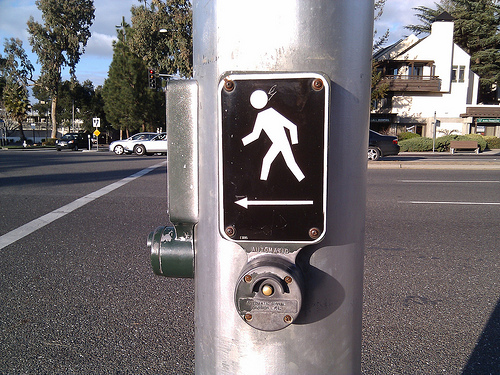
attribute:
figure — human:
[240, 90, 304, 182]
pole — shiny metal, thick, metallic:
[190, 0, 372, 371]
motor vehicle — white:
[134, 131, 166, 154]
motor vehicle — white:
[109, 130, 163, 154]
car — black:
[54, 130, 92, 150]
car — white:
[130, 134, 165, 157]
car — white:
[110, 129, 162, 157]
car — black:
[364, 128, 399, 161]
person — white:
[239, 85, 309, 187]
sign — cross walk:
[217, 70, 331, 247]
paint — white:
[2, 151, 142, 253]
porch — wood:
[377, 58, 442, 97]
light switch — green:
[145, 227, 200, 288]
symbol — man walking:
[236, 88, 308, 189]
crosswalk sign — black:
[217, 70, 331, 247]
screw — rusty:
[311, 74, 329, 94]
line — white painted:
[3, 150, 151, 231]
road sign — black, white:
[88, 111, 112, 127]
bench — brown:
[446, 136, 483, 157]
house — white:
[384, 15, 482, 139]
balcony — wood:
[376, 56, 463, 115]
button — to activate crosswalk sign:
[238, 249, 311, 333]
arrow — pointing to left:
[223, 182, 329, 222]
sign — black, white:
[210, 58, 354, 263]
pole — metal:
[125, 0, 379, 373]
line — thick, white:
[0, 133, 170, 268]